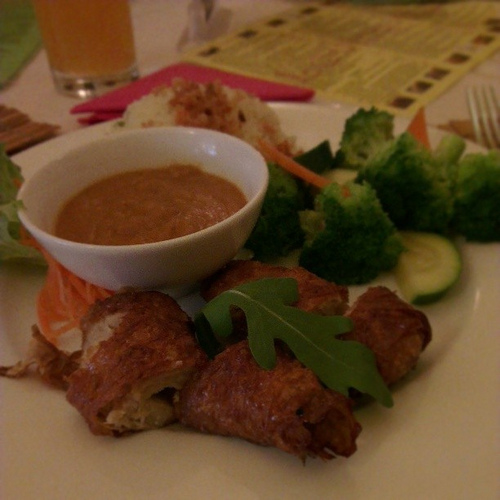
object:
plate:
[443, 294, 496, 488]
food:
[195, 339, 364, 462]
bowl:
[16, 118, 274, 270]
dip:
[96, 186, 201, 218]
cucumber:
[394, 226, 467, 301]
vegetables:
[340, 100, 388, 158]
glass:
[36, 0, 144, 106]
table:
[148, 3, 173, 55]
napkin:
[110, 47, 288, 111]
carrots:
[30, 300, 56, 330]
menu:
[218, 6, 485, 109]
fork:
[463, 80, 499, 156]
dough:
[84, 306, 182, 420]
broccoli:
[303, 175, 394, 281]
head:
[320, 190, 402, 278]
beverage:
[47, 6, 126, 72]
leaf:
[206, 276, 406, 406]